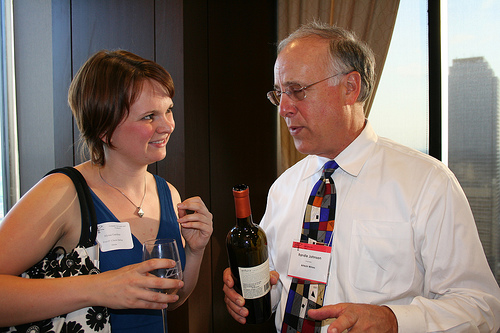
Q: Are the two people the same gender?
A: No, they are both male and female.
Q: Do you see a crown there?
A: No, there are no crowns.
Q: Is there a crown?
A: No, there are no crowns.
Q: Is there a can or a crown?
A: No, there are no crowns or cans.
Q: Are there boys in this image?
A: No, there are no boys.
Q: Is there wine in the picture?
A: Yes, there is wine.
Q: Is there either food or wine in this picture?
A: Yes, there is wine.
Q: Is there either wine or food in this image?
A: Yes, there is wine.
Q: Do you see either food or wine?
A: Yes, there is wine.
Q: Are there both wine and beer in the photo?
A: No, there is wine but no beer.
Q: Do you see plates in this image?
A: No, there are no plates.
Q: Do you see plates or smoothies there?
A: No, there are no plates or smoothies.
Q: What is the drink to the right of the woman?
A: The drink is wine.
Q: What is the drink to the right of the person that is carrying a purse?
A: The drink is wine.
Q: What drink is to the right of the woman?
A: The drink is wine.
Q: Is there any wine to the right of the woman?
A: Yes, there is wine to the right of the woman.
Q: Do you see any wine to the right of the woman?
A: Yes, there is wine to the right of the woman.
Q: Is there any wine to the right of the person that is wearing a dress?
A: Yes, there is wine to the right of the woman.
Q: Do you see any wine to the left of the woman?
A: No, the wine is to the right of the woman.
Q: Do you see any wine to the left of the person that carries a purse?
A: No, the wine is to the right of the woman.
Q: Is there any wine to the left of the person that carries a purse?
A: No, the wine is to the right of the woman.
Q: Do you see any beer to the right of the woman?
A: No, there is wine to the right of the woman.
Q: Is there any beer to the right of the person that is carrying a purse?
A: No, there is wine to the right of the woman.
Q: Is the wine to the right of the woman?
A: Yes, the wine is to the right of the woman.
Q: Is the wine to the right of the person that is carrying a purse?
A: Yes, the wine is to the right of the woman.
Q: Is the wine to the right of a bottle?
A: No, the wine is to the right of the woman.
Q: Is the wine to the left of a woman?
A: No, the wine is to the right of a woman.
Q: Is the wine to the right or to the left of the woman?
A: The wine is to the right of the woman.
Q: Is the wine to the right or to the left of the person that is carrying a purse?
A: The wine is to the right of the woman.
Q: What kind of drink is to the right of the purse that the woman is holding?
A: The drink is wine.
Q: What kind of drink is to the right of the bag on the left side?
A: The drink is wine.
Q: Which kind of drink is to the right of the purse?
A: The drink is wine.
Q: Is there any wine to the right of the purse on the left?
A: Yes, there is wine to the right of the purse.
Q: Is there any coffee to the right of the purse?
A: No, there is wine to the right of the purse.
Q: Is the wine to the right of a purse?
A: Yes, the wine is to the right of a purse.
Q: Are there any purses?
A: Yes, there is a purse.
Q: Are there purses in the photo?
A: Yes, there is a purse.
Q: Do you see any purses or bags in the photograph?
A: Yes, there is a purse.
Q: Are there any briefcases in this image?
A: No, there are no briefcases.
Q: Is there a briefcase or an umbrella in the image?
A: No, there are no briefcases or umbrellas.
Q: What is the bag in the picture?
A: The bag is a purse.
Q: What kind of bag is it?
A: The bag is a purse.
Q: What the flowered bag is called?
A: The bag is a purse.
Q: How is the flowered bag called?
A: The bag is a purse.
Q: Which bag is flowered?
A: The bag is a purse.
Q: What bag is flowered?
A: The bag is a purse.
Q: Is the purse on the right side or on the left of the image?
A: The purse is on the left of the image.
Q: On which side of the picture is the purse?
A: The purse is on the left of the image.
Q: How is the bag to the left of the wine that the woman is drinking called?
A: The bag is a purse.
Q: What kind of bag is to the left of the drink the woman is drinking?
A: The bag is a purse.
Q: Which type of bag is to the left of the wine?
A: The bag is a purse.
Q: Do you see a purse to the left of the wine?
A: Yes, there is a purse to the left of the wine.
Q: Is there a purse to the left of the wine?
A: Yes, there is a purse to the left of the wine.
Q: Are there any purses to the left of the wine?
A: Yes, there is a purse to the left of the wine.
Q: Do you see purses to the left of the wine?
A: Yes, there is a purse to the left of the wine.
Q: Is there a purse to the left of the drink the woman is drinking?
A: Yes, there is a purse to the left of the wine.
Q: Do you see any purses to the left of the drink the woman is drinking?
A: Yes, there is a purse to the left of the wine.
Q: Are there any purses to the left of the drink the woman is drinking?
A: Yes, there is a purse to the left of the wine.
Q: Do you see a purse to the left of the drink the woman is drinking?
A: Yes, there is a purse to the left of the wine.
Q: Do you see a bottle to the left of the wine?
A: No, there is a purse to the left of the wine.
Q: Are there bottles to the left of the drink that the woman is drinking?
A: No, there is a purse to the left of the wine.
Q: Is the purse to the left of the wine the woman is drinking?
A: Yes, the purse is to the left of the wine.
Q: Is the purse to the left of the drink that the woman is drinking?
A: Yes, the purse is to the left of the wine.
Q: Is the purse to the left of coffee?
A: No, the purse is to the left of the wine.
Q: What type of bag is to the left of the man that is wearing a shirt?
A: The bag is a purse.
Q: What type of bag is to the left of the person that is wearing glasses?
A: The bag is a purse.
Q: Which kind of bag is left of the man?
A: The bag is a purse.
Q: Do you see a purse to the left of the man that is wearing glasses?
A: Yes, there is a purse to the left of the man.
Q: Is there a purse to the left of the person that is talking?
A: Yes, there is a purse to the left of the man.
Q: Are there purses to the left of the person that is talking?
A: Yes, there is a purse to the left of the man.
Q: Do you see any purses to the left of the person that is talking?
A: Yes, there is a purse to the left of the man.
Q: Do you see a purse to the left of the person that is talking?
A: Yes, there is a purse to the left of the man.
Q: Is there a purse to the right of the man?
A: No, the purse is to the left of the man.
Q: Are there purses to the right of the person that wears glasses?
A: No, the purse is to the left of the man.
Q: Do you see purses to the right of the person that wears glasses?
A: No, the purse is to the left of the man.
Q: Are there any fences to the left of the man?
A: No, there is a purse to the left of the man.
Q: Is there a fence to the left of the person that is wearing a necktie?
A: No, there is a purse to the left of the man.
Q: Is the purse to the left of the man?
A: Yes, the purse is to the left of the man.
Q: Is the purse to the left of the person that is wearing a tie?
A: Yes, the purse is to the left of the man.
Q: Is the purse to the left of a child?
A: No, the purse is to the left of the man.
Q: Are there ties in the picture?
A: Yes, there is a tie.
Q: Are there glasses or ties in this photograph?
A: Yes, there is a tie.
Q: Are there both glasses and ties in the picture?
A: Yes, there are both a tie and glasses.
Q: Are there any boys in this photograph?
A: No, there are no boys.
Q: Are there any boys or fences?
A: No, there are no boys or fences.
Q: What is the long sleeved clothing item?
A: The clothing item is a shirt.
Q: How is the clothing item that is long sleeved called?
A: The clothing item is a shirt.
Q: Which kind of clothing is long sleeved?
A: The clothing is a shirt.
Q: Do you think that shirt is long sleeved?
A: Yes, the shirt is long sleeved.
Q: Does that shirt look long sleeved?
A: Yes, the shirt is long sleeved.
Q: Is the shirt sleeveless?
A: No, the shirt is long sleeved.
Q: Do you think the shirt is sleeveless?
A: No, the shirt is long sleeved.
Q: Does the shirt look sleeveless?
A: No, the shirt is long sleeved.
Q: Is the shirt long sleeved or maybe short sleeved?
A: The shirt is long sleeved.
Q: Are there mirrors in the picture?
A: No, there are no mirrors.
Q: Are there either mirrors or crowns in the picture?
A: No, there are no mirrors or crowns.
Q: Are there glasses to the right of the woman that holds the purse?
A: Yes, there are glasses to the right of the woman.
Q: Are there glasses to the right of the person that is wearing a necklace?
A: Yes, there are glasses to the right of the woman.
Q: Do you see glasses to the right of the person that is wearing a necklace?
A: Yes, there are glasses to the right of the woman.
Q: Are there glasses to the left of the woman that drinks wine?
A: No, the glasses are to the right of the woman.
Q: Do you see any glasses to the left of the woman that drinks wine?
A: No, the glasses are to the right of the woman.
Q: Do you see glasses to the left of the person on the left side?
A: No, the glasses are to the right of the woman.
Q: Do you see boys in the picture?
A: No, there are no boys.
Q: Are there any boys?
A: No, there are no boys.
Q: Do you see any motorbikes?
A: No, there are no motorbikes.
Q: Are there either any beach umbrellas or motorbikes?
A: No, there are no motorbikes or beach umbrellas.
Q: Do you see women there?
A: Yes, there is a woman.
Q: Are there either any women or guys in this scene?
A: Yes, there is a woman.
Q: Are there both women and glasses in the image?
A: Yes, there are both a woman and glasses.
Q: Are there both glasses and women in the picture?
A: Yes, there are both a woman and glasses.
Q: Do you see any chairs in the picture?
A: No, there are no chairs.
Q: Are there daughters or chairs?
A: No, there are no chairs or daughters.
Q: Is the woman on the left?
A: Yes, the woman is on the left of the image.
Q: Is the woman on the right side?
A: No, the woman is on the left of the image.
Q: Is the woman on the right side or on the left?
A: The woman is on the left of the image.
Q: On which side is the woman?
A: The woman is on the left of the image.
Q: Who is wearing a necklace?
A: The woman is wearing a necklace.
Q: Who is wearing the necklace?
A: The woman is wearing a necklace.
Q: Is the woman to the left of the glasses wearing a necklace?
A: Yes, the woman is wearing a necklace.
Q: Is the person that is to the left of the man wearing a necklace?
A: Yes, the woman is wearing a necklace.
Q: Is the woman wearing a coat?
A: No, the woman is wearing a necklace.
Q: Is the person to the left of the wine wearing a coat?
A: No, the woman is wearing a necklace.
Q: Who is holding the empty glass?
A: The woman is holding the glass.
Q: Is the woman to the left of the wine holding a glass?
A: Yes, the woman is holding a glass.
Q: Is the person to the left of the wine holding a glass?
A: Yes, the woman is holding a glass.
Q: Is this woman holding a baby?
A: No, the woman is holding a glass.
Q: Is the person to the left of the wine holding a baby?
A: No, the woman is holding a glass.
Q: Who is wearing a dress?
A: The woman is wearing a dress.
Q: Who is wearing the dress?
A: The woman is wearing a dress.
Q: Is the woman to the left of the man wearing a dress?
A: Yes, the woman is wearing a dress.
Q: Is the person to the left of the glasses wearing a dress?
A: Yes, the woman is wearing a dress.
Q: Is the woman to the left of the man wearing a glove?
A: No, the woman is wearing a dress.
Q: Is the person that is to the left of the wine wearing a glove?
A: No, the woman is wearing a dress.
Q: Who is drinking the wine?
A: The woman is drinking the wine.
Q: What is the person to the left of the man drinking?
A: The woman is drinking wine.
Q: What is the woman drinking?
A: The woman is drinking wine.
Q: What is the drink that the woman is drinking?
A: The drink is wine.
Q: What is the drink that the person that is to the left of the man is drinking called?
A: The drink is wine.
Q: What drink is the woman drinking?
A: The woman is drinking wine.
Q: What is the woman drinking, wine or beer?
A: The woman is drinking wine.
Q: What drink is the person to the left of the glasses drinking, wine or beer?
A: The woman is drinking wine.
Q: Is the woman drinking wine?
A: Yes, the woman is drinking wine.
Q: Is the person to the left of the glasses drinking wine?
A: Yes, the woman is drinking wine.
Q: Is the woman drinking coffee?
A: No, the woman is drinking wine.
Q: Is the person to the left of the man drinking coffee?
A: No, the woman is drinking wine.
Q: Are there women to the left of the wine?
A: Yes, there is a woman to the left of the wine.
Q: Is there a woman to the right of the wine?
A: No, the woman is to the left of the wine.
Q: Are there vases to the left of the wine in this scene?
A: No, there is a woman to the left of the wine.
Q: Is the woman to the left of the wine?
A: Yes, the woman is to the left of the wine.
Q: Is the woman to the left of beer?
A: No, the woman is to the left of the wine.